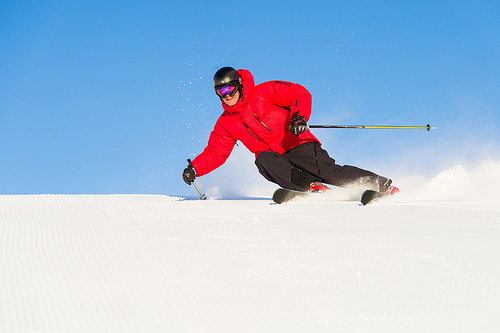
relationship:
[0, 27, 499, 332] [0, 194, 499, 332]
snow has lines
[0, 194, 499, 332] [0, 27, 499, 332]
lines on snow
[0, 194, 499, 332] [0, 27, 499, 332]
lines in snow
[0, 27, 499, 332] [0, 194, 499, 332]
snow marked with lines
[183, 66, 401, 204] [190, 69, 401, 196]
man wearing red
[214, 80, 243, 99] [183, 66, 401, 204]
goggles on man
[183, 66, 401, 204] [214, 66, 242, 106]
man has a head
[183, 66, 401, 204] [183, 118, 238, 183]
man has an arm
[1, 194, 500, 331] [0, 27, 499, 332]
ground covered in snow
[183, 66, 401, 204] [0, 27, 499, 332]
man on snow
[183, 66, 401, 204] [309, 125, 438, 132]
man holding pole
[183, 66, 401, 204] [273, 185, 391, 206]
man on skis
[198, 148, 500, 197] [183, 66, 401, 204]
snow behind man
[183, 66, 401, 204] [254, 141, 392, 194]
man wearing black pants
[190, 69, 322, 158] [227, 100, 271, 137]
sweatshirt has strings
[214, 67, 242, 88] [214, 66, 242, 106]
helmet on mans head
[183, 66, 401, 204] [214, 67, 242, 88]
man wearing a helmet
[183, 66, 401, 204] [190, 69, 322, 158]
man wearing a sweatshirt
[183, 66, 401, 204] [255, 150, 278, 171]
man has a knee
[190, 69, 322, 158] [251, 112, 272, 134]
sweatshirt has a zipper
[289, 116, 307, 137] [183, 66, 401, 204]
glove on man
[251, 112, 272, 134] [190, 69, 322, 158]
zipper on sweatshirt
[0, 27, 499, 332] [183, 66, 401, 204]
snow under man